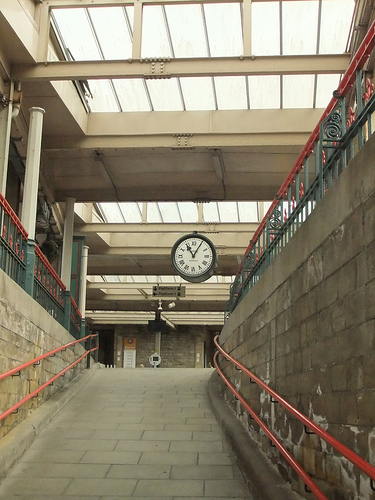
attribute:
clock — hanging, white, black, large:
[169, 232, 218, 283]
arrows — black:
[193, 238, 202, 259]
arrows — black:
[186, 241, 194, 259]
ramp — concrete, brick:
[0, 365, 265, 499]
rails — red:
[208, 336, 373, 499]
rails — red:
[0, 332, 102, 419]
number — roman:
[192, 238, 198, 247]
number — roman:
[202, 247, 208, 253]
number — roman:
[203, 252, 211, 260]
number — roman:
[201, 260, 208, 266]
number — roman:
[191, 265, 197, 272]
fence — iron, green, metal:
[1, 197, 99, 353]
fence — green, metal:
[221, 25, 373, 317]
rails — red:
[2, 192, 85, 321]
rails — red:
[238, 24, 373, 270]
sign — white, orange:
[122, 333, 136, 367]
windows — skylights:
[51, 0, 365, 116]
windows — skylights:
[74, 200, 316, 225]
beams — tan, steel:
[13, 54, 374, 87]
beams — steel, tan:
[73, 221, 269, 232]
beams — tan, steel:
[87, 280, 233, 292]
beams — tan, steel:
[84, 311, 226, 321]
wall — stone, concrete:
[112, 325, 213, 366]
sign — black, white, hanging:
[154, 285, 186, 295]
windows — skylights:
[87, 274, 235, 285]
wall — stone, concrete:
[216, 132, 373, 499]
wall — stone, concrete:
[2, 268, 101, 483]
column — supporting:
[19, 106, 47, 248]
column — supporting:
[59, 195, 79, 295]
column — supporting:
[77, 245, 89, 321]